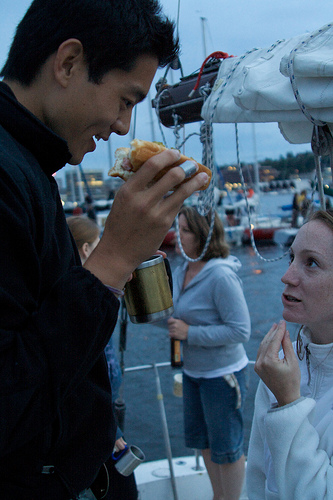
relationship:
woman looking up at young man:
[240, 208, 332, 500] [2, 9, 206, 488]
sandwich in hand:
[107, 138, 214, 190] [101, 148, 212, 261]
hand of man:
[101, 148, 212, 261] [1, 1, 212, 498]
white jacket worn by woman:
[248, 337, 329, 489] [268, 228, 326, 499]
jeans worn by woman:
[176, 352, 254, 469] [153, 197, 253, 498]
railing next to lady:
[124, 361, 191, 473] [163, 202, 259, 450]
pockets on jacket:
[47, 374, 118, 488] [0, 80, 123, 499]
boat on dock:
[219, 197, 279, 249] [60, 178, 292, 246]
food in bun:
[106, 137, 216, 206] [106, 137, 214, 192]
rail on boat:
[122, 361, 185, 498] [132, 452, 247, 498]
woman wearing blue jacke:
[153, 197, 253, 498] [166, 256, 248, 373]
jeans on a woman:
[176, 352, 254, 469] [153, 197, 253, 498]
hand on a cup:
[114, 434, 126, 452] [111, 443, 145, 477]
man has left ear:
[1, 1, 212, 498] [53, 37, 82, 87]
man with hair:
[1, 1, 212, 498] [1, 0, 181, 88]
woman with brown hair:
[153, 197, 253, 498] [176, 202, 228, 263]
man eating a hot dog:
[1, 1, 212, 498] [109, 138, 211, 184]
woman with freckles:
[276, 208, 331, 337] [302, 271, 331, 297]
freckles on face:
[302, 271, 331, 297] [282, 209, 332, 344]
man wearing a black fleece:
[1, 1, 212, 498] [0, 80, 118, 495]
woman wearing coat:
[153, 197, 253, 498] [165, 251, 253, 348]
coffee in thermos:
[131, 256, 172, 288] [109, 247, 181, 322]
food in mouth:
[123, 147, 195, 182] [279, 290, 306, 306]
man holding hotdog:
[1, 1, 212, 498] [115, 140, 216, 188]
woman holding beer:
[153, 197, 253, 498] [171, 326, 180, 365]